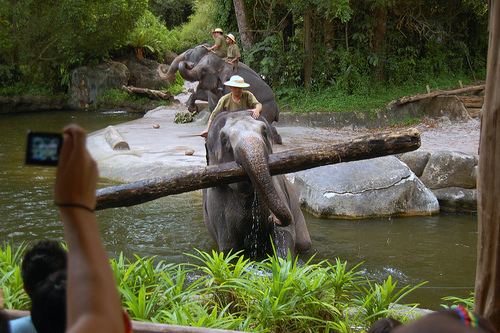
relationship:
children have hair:
[2, 227, 132, 332] [22, 236, 67, 331]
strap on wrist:
[56, 201, 94, 211] [55, 193, 95, 229]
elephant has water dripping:
[195, 102, 312, 260] [249, 187, 265, 259]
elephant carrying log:
[195, 102, 312, 260] [91, 123, 427, 207]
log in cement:
[101, 118, 127, 150] [87, 115, 433, 219]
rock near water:
[87, 91, 484, 216] [1, 107, 488, 306]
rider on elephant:
[202, 68, 266, 145] [195, 102, 312, 260]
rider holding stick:
[202, 68, 266, 145] [176, 129, 207, 140]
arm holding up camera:
[55, 126, 127, 329] [23, 129, 67, 165]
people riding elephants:
[208, 26, 247, 64] [177, 54, 292, 127]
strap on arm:
[56, 201, 94, 211] [55, 126, 127, 329]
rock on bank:
[87, 91, 484, 216] [4, 50, 483, 129]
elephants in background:
[177, 54, 292, 127] [2, 5, 489, 142]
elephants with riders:
[155, 39, 322, 261] [207, 25, 263, 140]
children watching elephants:
[11, 235, 132, 332] [155, 39, 322, 261]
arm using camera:
[55, 126, 127, 329] [23, 129, 67, 165]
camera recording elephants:
[23, 129, 67, 165] [155, 39, 322, 261]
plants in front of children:
[2, 240, 402, 331] [11, 235, 132, 332]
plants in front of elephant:
[2, 240, 402, 331] [195, 102, 312, 260]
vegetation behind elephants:
[1, 2, 482, 112] [155, 39, 322, 261]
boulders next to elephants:
[66, 51, 175, 109] [177, 54, 292, 127]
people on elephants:
[208, 26, 247, 64] [177, 54, 292, 127]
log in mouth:
[91, 123, 427, 207] [230, 141, 270, 179]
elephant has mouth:
[195, 102, 312, 260] [230, 141, 270, 179]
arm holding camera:
[55, 126, 127, 329] [23, 129, 67, 165]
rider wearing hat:
[202, 68, 266, 145] [219, 74, 253, 91]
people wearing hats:
[208, 26, 247, 64] [213, 27, 238, 42]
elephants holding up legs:
[177, 54, 292, 127] [185, 86, 223, 113]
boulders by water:
[66, 51, 175, 109] [1, 107, 488, 306]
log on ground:
[101, 118, 127, 150] [70, 98, 428, 221]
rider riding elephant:
[202, 68, 266, 145] [195, 102, 312, 260]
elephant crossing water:
[195, 102, 312, 260] [1, 107, 488, 306]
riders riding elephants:
[207, 25, 263, 140] [155, 39, 322, 261]